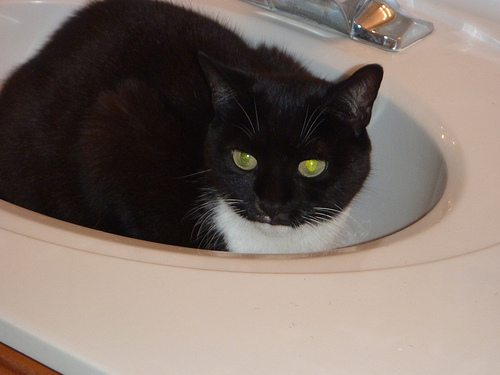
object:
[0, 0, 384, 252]
cat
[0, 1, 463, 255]
sink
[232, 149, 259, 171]
eyes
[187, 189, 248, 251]
whiskers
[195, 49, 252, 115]
ears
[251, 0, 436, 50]
faucet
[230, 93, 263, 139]
whiskers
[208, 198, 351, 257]
patch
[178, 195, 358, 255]
chest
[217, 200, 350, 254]
white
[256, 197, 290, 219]
nose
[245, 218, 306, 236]
mouth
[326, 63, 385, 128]
ear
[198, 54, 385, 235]
head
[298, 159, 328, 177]
eye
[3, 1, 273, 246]
fur